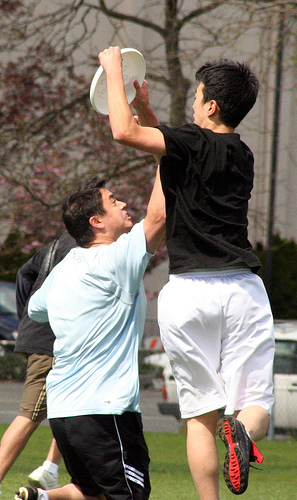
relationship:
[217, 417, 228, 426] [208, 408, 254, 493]
nub on bottom of cleat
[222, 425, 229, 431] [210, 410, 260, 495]
nub on bottom of cleat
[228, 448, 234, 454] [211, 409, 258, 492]
nub on bottom of cleat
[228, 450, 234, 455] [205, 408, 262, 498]
nub on bottom of cleat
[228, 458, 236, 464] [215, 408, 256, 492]
nub on bottom of cleat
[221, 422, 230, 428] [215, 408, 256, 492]
nub on bottom of cleat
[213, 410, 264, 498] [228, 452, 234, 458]
cleat has nub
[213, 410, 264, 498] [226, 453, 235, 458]
cleat has nub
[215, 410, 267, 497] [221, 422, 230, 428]
shoe has nub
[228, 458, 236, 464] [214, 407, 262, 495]
nub on shoe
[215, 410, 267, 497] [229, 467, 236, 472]
shoe has bump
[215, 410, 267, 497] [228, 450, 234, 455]
shoe has nub